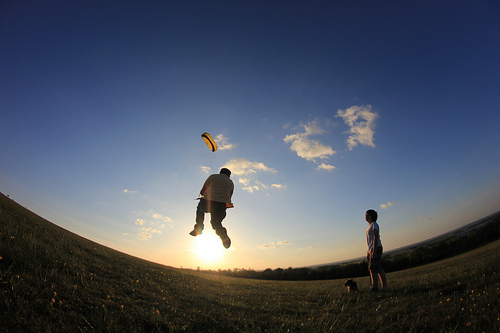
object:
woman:
[363, 208, 389, 287]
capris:
[367, 246, 384, 275]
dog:
[343, 278, 358, 293]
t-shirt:
[364, 222, 384, 253]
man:
[189, 167, 238, 250]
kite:
[198, 130, 219, 154]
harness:
[198, 174, 217, 198]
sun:
[192, 235, 225, 263]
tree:
[258, 268, 273, 280]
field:
[35, 242, 97, 282]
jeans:
[196, 200, 228, 228]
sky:
[24, 23, 88, 54]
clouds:
[282, 117, 337, 173]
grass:
[264, 302, 310, 314]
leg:
[194, 207, 205, 224]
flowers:
[48, 297, 57, 305]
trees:
[285, 266, 303, 280]